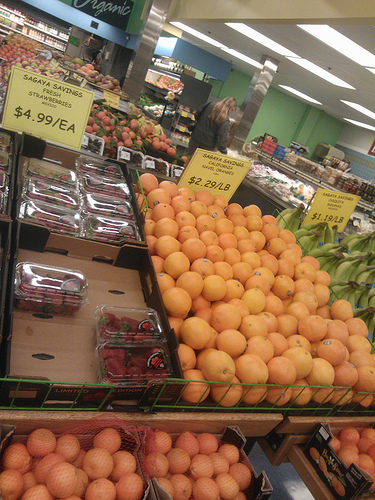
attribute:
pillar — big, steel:
[223, 50, 281, 153]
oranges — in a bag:
[7, 422, 157, 498]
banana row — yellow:
[304, 247, 373, 286]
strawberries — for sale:
[21, 139, 172, 385]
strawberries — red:
[83, 300, 154, 336]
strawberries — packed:
[11, 259, 90, 316]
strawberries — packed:
[92, 302, 166, 345]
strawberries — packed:
[83, 209, 142, 244]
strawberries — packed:
[80, 189, 136, 221]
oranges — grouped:
[327, 418, 374, 496]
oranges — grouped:
[142, 422, 253, 498]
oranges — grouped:
[2, 424, 144, 497]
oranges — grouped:
[132, 170, 374, 404]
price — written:
[16, 106, 76, 134]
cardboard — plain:
[9, 225, 153, 381]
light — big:
[220, 44, 264, 70]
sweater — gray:
[191, 101, 233, 141]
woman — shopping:
[189, 94, 238, 163]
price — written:
[188, 175, 231, 191]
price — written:
[2, 64, 118, 158]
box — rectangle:
[127, 160, 363, 407]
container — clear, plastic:
[90, 302, 167, 349]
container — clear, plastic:
[89, 337, 177, 386]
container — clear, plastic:
[8, 258, 90, 320]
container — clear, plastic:
[77, 207, 143, 246]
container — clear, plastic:
[69, 151, 126, 183]